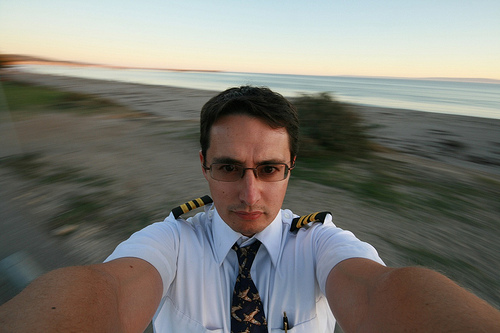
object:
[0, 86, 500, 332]
man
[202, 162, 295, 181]
glasses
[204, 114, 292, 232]
face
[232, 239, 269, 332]
tie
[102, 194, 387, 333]
shirt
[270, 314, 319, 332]
pocket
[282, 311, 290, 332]
pen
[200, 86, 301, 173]
hair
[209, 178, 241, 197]
cheek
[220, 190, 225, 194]
mole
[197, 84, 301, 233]
head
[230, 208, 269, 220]
mouth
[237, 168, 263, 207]
nose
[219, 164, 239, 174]
eye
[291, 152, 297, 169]
ear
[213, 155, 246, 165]
eyebrow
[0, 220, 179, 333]
arm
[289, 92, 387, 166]
bush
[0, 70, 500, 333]
beach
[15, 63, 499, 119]
water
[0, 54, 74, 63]
hillside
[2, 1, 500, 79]
sky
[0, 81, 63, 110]
grass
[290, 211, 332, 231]
epaulette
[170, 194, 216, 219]
epaulette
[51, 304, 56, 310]
freckle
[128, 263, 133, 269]
freckle